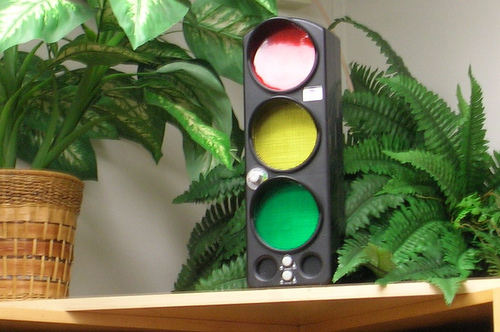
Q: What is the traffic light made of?
A: Plastic.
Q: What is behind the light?
A: Basket.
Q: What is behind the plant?
A: White wall.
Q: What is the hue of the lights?
A: Red yellow and green.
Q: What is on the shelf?
A: A traffic light.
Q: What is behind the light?
A: A green fern.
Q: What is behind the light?
A: Green plants.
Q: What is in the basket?
A: A plant.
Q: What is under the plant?
A: A shelf.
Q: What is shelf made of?
A: Wood.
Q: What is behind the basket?
A: A wall.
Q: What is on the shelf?
A: Plants and a light.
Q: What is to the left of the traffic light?
A: A plant.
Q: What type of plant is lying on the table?
A: A fern.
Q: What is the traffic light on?
A: A shelf.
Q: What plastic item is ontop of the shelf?
A: A trafic light.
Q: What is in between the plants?
A: A traffic light.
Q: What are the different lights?
A: Red, yellow and green.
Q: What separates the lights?
A: A black case.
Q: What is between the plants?
A: A light on a table.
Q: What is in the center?
A: A traffic light on a table.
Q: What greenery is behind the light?
A: Plants.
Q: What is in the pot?
A: A plant.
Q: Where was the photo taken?
A: In a room.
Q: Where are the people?
A: None in photo.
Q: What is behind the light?
A: A fern.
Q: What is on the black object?
A: Three lights.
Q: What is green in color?
A: One light.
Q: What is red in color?
A: One light.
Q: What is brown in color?
A: Basket.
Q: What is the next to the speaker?
A: Plants.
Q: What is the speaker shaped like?
A: Traffic signal.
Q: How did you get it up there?
A: Ladder.